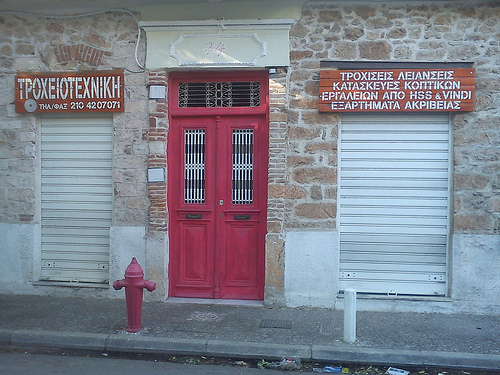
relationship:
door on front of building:
[163, 65, 273, 311] [3, 3, 499, 315]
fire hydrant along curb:
[113, 257, 160, 337] [0, 323, 499, 374]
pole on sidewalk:
[340, 286, 362, 343] [1, 287, 500, 373]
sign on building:
[317, 69, 481, 117] [3, 3, 499, 315]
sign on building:
[16, 68, 126, 116] [3, 3, 499, 315]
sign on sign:
[317, 69, 474, 113] [317, 69, 481, 117]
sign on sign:
[16, 71, 126, 116] [16, 68, 126, 116]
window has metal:
[332, 110, 460, 304] [338, 112, 452, 300]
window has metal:
[28, 112, 117, 295] [40, 115, 108, 287]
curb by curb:
[6, 323, 499, 374] [0, 323, 499, 374]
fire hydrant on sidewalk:
[113, 257, 160, 337] [1, 287, 500, 373]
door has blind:
[163, 65, 273, 311] [226, 127, 254, 205]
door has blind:
[163, 65, 273, 311] [183, 127, 208, 208]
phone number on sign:
[69, 101, 123, 111] [16, 68, 126, 116]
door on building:
[163, 65, 273, 311] [3, 3, 499, 315]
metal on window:
[338, 112, 452, 300] [332, 110, 460, 304]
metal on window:
[40, 115, 108, 287] [28, 112, 117, 295]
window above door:
[175, 81, 261, 111] [163, 65, 273, 311]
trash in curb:
[239, 359, 470, 375] [0, 323, 499, 374]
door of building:
[163, 65, 273, 311] [3, 3, 499, 315]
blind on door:
[226, 127, 254, 205] [163, 65, 273, 311]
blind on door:
[183, 127, 208, 208] [163, 65, 273, 311]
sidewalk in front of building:
[1, 287, 500, 373] [3, 3, 499, 315]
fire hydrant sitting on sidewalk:
[113, 257, 160, 337] [1, 287, 500, 373]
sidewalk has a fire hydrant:
[1, 287, 500, 373] [113, 257, 160, 337]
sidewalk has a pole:
[1, 287, 500, 373] [340, 286, 362, 343]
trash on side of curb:
[239, 359, 470, 375] [0, 323, 499, 374]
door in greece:
[163, 65, 273, 311] [2, 5, 498, 365]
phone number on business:
[69, 101, 123, 111] [10, 18, 486, 316]